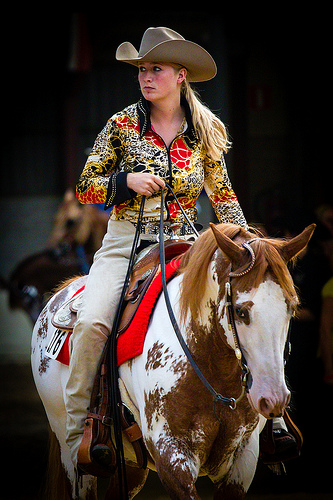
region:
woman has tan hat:
[118, 34, 231, 70]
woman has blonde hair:
[171, 58, 236, 158]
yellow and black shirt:
[83, 122, 236, 239]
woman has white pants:
[70, 211, 154, 416]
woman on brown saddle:
[108, 213, 196, 350]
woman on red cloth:
[102, 260, 178, 349]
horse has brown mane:
[210, 200, 302, 334]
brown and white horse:
[126, 299, 237, 465]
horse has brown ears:
[156, 200, 332, 285]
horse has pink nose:
[212, 375, 294, 455]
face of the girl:
[113, 24, 212, 120]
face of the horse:
[212, 210, 329, 484]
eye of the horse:
[228, 301, 271, 343]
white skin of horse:
[258, 315, 280, 377]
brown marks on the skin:
[139, 334, 187, 388]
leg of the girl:
[25, 234, 119, 374]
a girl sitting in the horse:
[64, 25, 289, 489]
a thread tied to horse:
[132, 263, 248, 439]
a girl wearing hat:
[106, 14, 216, 75]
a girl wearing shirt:
[70, 103, 307, 272]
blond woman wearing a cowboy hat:
[114, 24, 231, 152]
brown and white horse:
[24, 222, 316, 497]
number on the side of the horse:
[46, 327, 66, 359]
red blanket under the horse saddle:
[121, 289, 146, 357]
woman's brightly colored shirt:
[76, 95, 248, 235]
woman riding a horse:
[74, 25, 247, 472]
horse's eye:
[234, 305, 245, 320]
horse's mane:
[190, 236, 213, 311]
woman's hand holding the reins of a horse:
[124, 173, 187, 249]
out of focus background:
[1, 138, 76, 273]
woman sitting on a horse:
[10, 4, 325, 492]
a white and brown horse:
[29, 219, 301, 493]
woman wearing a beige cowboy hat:
[78, 29, 221, 82]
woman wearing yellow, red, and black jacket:
[64, 102, 266, 232]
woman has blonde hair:
[130, 61, 232, 156]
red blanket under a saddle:
[42, 251, 178, 357]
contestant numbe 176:
[35, 312, 61, 354]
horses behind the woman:
[5, 170, 101, 302]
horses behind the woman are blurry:
[1, 186, 98, 300]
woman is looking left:
[91, 55, 208, 230]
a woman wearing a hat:
[118, 25, 214, 87]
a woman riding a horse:
[112, 32, 270, 497]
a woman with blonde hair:
[160, 63, 211, 165]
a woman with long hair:
[170, 73, 235, 154]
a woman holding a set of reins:
[135, 168, 180, 228]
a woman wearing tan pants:
[91, 223, 133, 333]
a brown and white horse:
[162, 243, 276, 408]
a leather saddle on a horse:
[121, 210, 189, 323]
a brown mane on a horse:
[173, 213, 243, 317]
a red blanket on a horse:
[116, 253, 178, 372]